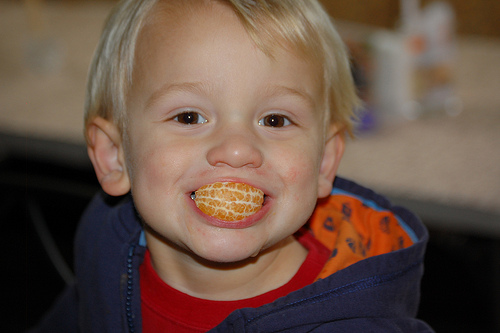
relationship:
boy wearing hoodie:
[33, 2, 435, 333] [55, 180, 430, 323]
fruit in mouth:
[194, 181, 265, 220] [185, 176, 275, 224]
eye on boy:
[167, 110, 211, 126] [33, 2, 435, 333]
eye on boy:
[257, 113, 299, 129] [33, 2, 435, 333]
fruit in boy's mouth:
[194, 181, 265, 220] [174, 173, 281, 233]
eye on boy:
[262, 107, 298, 128] [33, 2, 435, 331]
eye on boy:
[167, 105, 215, 131] [33, 2, 435, 331]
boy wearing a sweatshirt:
[33, 2, 435, 331] [40, 179, 437, 331]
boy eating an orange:
[33, 2, 435, 331] [187, 183, 265, 223]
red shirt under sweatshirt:
[139, 232, 330, 326] [40, 179, 437, 331]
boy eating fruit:
[33, 2, 435, 331] [186, 173, 269, 225]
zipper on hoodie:
[125, 231, 145, 331] [43, 180, 453, 328]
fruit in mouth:
[194, 181, 265, 220] [190, 173, 285, 228]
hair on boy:
[82, 2, 372, 147] [33, 2, 435, 331]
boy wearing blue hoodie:
[33, 2, 435, 331] [31, 171, 437, 333]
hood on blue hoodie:
[239, 175, 436, 327] [31, 171, 437, 333]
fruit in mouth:
[194, 181, 265, 220] [189, 175, 271, 230]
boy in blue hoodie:
[33, 2, 435, 333] [31, 171, 436, 331]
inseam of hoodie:
[306, 192, 411, 282] [71, 168, 429, 331]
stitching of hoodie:
[278, 272, 384, 307] [299, 157, 455, 314]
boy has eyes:
[33, 2, 435, 333] [138, 79, 323, 144]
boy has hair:
[33, 2, 435, 331] [82, 2, 372, 147]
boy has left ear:
[33, 2, 435, 333] [88, 107, 125, 199]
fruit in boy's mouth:
[194, 181, 265, 220] [185, 177, 275, 228]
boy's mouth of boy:
[185, 177, 275, 228] [95, 9, 400, 319]